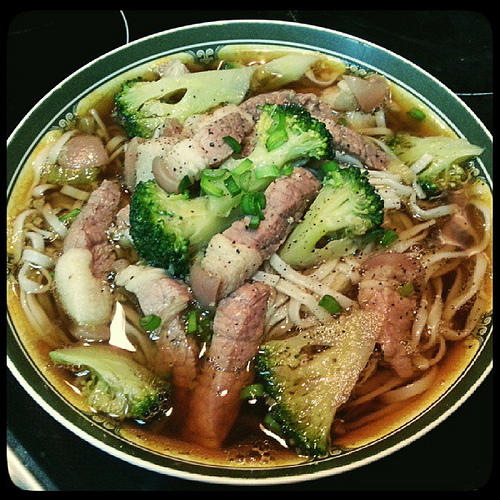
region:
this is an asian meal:
[23, 39, 464, 476]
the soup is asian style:
[23, 75, 465, 448]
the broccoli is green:
[22, 96, 482, 481]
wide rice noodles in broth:
[21, 105, 471, 427]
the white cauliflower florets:
[47, 205, 182, 370]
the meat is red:
[59, 133, 492, 473]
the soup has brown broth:
[47, 100, 464, 442]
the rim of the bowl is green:
[397, 351, 493, 433]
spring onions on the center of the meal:
[8, 30, 498, 474]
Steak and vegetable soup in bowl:
[2, 19, 498, 487]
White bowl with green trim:
[7, 20, 498, 487]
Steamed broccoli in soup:
[125, 101, 392, 280]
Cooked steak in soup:
[187, 285, 263, 447]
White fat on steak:
[200, 234, 261, 294]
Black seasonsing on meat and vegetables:
[165, 126, 333, 283]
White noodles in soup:
[17, 165, 77, 350]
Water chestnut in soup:
[53, 247, 114, 328]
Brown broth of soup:
[155, 391, 397, 453]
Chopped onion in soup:
[195, 133, 269, 229]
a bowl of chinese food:
[5, 18, 497, 485]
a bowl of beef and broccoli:
[0, 20, 497, 497]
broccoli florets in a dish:
[122, 79, 392, 456]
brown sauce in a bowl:
[134, 380, 323, 475]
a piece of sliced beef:
[194, 287, 268, 452]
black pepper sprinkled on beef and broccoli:
[140, 82, 470, 327]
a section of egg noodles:
[257, 254, 355, 336]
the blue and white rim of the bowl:
[7, 320, 495, 494]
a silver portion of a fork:
[7, 436, 50, 492]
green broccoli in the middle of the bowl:
[128, 101, 382, 293]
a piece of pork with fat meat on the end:
[195, 171, 318, 301]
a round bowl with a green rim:
[4, 18, 495, 488]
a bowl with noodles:
[0, 22, 499, 487]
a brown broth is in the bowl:
[7, 20, 492, 492]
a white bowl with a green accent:
[11, 14, 492, 487]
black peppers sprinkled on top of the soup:
[116, 98, 396, 309]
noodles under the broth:
[398, 200, 494, 387]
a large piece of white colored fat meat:
[49, 248, 114, 330]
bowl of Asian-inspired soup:
[3, 18, 496, 488]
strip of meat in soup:
[182, 279, 273, 450]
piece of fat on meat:
[201, 231, 263, 295]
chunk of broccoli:
[247, 303, 396, 451]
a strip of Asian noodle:
[406, 201, 461, 219]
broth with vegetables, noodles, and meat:
[3, 43, 499, 468]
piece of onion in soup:
[338, 74, 390, 112]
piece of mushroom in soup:
[61, 135, 108, 170]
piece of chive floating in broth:
[405, 106, 429, 124]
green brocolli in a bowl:
[283, 182, 372, 265]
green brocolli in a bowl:
[262, 297, 387, 437]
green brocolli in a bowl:
[38, 341, 148, 406]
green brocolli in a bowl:
[132, 186, 211, 256]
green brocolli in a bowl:
[237, 118, 297, 190]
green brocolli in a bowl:
[140, 74, 252, 139]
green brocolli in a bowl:
[50, 331, 189, 446]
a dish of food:
[2, 30, 494, 488]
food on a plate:
[3, 7, 497, 480]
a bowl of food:
[0, 37, 493, 487]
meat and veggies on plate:
[8, 42, 495, 440]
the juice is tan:
[369, 95, 444, 172]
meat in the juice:
[175, 273, 280, 454]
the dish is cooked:
[0, 13, 497, 488]